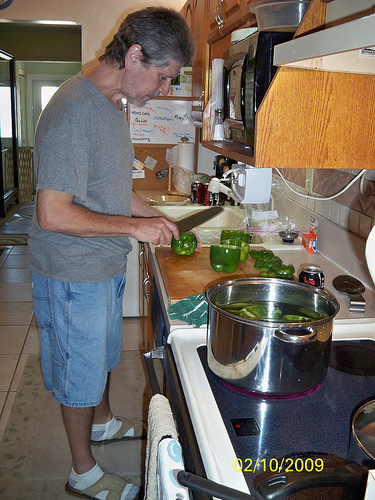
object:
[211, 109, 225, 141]
salt shaker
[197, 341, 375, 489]
top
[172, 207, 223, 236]
knife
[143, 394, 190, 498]
towel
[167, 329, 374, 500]
stove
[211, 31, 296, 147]
microwave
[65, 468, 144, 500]
sandal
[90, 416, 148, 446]
sandal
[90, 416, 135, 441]
sock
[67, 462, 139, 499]
sock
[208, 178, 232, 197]
faucet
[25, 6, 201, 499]
man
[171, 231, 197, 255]
pepper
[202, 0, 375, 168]
shelf